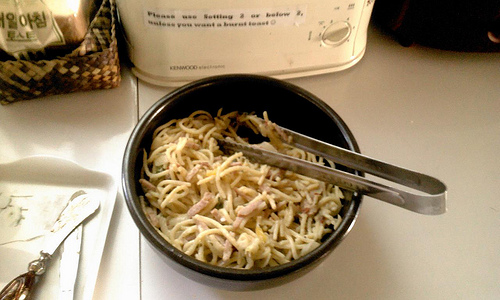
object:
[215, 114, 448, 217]
tongs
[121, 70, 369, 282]
bowl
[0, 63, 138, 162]
shade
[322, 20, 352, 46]
handle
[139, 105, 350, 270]
pasta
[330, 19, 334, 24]
number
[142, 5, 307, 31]
sign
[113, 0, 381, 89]
toaster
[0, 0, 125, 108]
basket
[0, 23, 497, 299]
counter